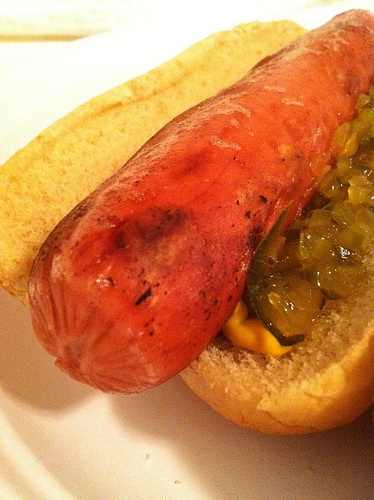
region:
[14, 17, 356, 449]
A cooked hot dog with relish and mustard.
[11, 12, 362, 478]
A cooked hot dog with relish and mustard inside a bun.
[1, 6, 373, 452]
a cooked hot dog on a bun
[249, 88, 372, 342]
green relish on a bun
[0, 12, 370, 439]
a white hot dog bun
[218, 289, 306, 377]
mustard under relish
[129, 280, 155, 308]
a burnt spot on a hot dog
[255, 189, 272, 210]
a burnt spot on a hot dog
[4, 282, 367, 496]
a white plate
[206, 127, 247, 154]
a bubble on a hot dog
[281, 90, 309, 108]
a bubble on a hot dog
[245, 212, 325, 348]
a piece of relish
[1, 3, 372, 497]
hot dog on a plate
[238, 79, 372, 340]
relish on the hot dog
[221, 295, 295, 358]
mustard on the hot dog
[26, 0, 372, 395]
the hot dog has been cooked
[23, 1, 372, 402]
the hot dog has a casing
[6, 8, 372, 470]
hot dog is on a bun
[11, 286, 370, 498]
white paper plate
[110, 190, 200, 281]
black spot on the hot dog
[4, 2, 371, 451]
hot dog bun is yellow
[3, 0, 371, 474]
delicious looking hot dog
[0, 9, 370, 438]
hot dog on a bun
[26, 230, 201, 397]
tip of a hot dog sitting on bun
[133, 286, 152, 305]
charcoal from grill on hot dog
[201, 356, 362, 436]
tip of bun siting on white plate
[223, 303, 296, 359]
mustard underneeth relish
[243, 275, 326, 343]
relish on top of mustard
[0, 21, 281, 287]
side of bun that hot dog is in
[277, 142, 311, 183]
blister on hot dog from fire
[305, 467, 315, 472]
bun crumb on white plate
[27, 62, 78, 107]
white plate that hot dog and bun is sitting on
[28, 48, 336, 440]
a hotdog on a table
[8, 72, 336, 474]
a cooked hotdog on the table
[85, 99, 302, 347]
a cooked hotdog on a bun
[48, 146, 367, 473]
a hotdog on a bun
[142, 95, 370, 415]
a hotdog with relish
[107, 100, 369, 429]
a hotdog with green relish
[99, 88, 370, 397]
a hotdog with mustard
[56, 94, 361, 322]
a hotdog with yellow mustard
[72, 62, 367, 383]
a hotdog with toppings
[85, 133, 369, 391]
a bun with cooked hotdgo